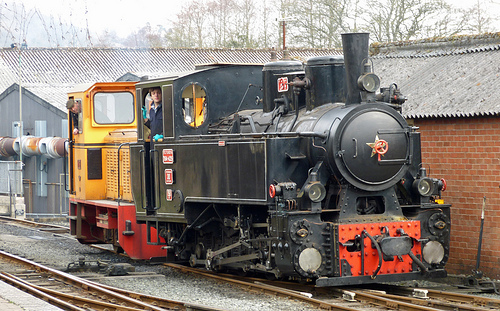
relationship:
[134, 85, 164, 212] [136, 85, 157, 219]
man in door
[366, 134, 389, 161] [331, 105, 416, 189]
image on circle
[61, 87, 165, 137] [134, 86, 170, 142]
men looking out openings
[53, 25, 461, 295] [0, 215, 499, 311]
train on gravel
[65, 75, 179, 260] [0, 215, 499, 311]
train car on gravel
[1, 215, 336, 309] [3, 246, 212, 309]
gravel between tracks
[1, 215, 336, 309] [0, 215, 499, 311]
gravel between gravel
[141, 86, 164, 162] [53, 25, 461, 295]
man on train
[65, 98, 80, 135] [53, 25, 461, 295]
men on train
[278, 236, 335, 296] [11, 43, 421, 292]
light on train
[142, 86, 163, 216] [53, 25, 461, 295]
door on train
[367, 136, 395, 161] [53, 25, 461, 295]
image on train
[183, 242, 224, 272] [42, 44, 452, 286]
wheels on train